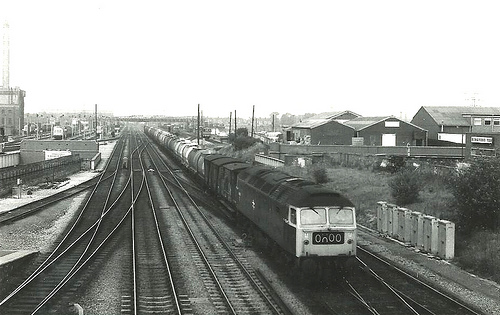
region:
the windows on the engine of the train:
[296, 206, 353, 228]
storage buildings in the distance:
[290, 116, 432, 153]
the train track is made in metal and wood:
[119, 128, 182, 308]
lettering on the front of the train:
[314, 231, 341, 248]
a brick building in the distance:
[4, 86, 104, 181]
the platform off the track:
[0, 167, 80, 224]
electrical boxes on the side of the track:
[372, 201, 459, 258]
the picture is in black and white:
[5, 4, 497, 311]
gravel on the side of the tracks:
[364, 226, 494, 314]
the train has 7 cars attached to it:
[142, 121, 372, 281]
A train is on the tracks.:
[130, 115, 391, 311]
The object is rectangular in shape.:
[435, 216, 458, 256]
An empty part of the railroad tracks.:
[3, 137, 270, 312]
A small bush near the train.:
[385, 165, 421, 200]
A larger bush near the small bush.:
[441, 150, 497, 225]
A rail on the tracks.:
[143, 180, 188, 313]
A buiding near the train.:
[287, 103, 438, 144]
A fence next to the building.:
[265, 135, 466, 160]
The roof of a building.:
[418, 95, 499, 126]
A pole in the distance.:
[193, 98, 205, 149]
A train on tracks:
[143, 125, 358, 275]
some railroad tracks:
[0, 129, 280, 311]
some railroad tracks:
[326, 243, 470, 312]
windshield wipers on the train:
[308, 203, 343, 216]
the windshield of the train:
[301, 205, 353, 224]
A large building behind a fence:
[289, 118, 356, 143]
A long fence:
[292, 144, 464, 154]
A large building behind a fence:
[344, 113, 428, 148]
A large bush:
[452, 150, 496, 233]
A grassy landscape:
[286, 161, 499, 275]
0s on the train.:
[308, 229, 353, 250]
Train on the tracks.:
[153, 125, 361, 257]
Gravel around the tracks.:
[177, 250, 282, 312]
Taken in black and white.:
[5, 27, 496, 312]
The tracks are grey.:
[336, 275, 446, 310]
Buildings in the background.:
[290, 87, 499, 165]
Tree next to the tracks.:
[458, 160, 499, 234]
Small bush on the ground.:
[306, 157, 334, 187]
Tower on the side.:
[0, 13, 27, 103]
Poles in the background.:
[189, 95, 289, 152]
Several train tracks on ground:
[100, 157, 198, 279]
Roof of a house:
[342, 112, 412, 133]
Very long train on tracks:
[142, 113, 369, 283]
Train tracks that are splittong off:
[24, 178, 155, 294]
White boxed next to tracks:
[369, 195, 467, 262]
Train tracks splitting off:
[345, 276, 432, 311]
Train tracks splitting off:
[117, 137, 167, 188]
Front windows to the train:
[299, 206, 360, 226]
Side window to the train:
[283, 200, 302, 230]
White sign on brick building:
[464, 134, 499, 151]